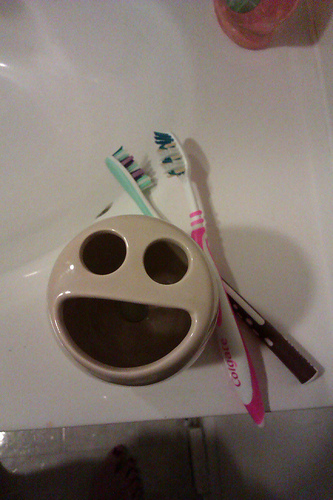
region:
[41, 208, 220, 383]
Toothbrush holder that looks like a face.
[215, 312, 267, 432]
Handle of a pink and white toothbrush.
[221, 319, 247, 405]
Colegate manufactured the toothbrush.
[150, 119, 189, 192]
Bristles on the toothbrush.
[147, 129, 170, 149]
Blue bristles on the toothbrush.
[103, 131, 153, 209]
A pale green and white toothbrush.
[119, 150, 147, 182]
Purple bristles on the toothbrush.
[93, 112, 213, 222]
Two brushes on the sink.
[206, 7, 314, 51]
Part of a soap bottle.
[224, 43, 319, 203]
A very white sink.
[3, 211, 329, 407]
smooth counter of the sink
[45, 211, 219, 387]
toothbrush holder meant for two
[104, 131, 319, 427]
two toothbrushes sit on the counter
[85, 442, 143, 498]
a woman's foot with painted toes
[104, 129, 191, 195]
the toothbrush bristles show use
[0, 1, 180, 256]
the sink is empty of water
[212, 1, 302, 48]
a small plant decorates the counter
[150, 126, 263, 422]
the woman uses a Colgate toothbrush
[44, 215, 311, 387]
the bathroom light casts shadows from the holder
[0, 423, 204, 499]
the bathroom floor is clean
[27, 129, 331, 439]
two toothbrushes and a toothbrush holder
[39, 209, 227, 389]
a ceramic toothbrush holder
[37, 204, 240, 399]
ceramic toothbrush holder that resembles a smiley face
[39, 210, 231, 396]
a toothbrush holder resembling a smiling face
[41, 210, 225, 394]
toothbrush holder that looks like a smiley face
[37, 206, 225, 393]
a ceramic toothbrush holder that looks like it is smiling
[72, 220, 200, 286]
holes of a toothbrush holder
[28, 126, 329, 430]
two toothbrushes next to a toothbrush holder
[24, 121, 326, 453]
two toothbrushes next to a ceramic toothbrush holder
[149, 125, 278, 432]
a pink toothbrush on its side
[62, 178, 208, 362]
tan cup for toothbrushes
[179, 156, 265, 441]
pink and white brush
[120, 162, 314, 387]
purple and green brush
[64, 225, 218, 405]
cup on white lavatory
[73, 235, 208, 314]
two circular holes in cup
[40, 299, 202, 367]
one semi-circle hole in cup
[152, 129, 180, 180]
blue and white bristles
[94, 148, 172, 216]
green and white bristles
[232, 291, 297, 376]
purple handle on brush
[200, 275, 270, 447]
pink and white handle